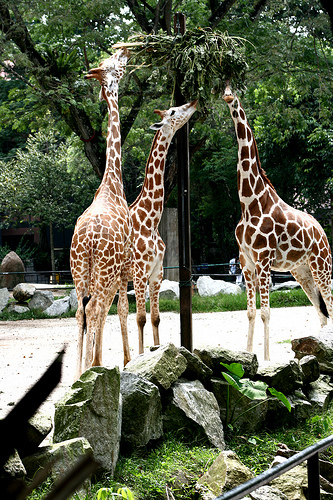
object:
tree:
[0, 127, 101, 288]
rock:
[195, 273, 239, 296]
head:
[147, 101, 198, 139]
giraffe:
[90, 100, 198, 369]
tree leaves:
[288, 110, 296, 122]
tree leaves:
[198, 159, 209, 173]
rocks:
[12, 283, 36, 302]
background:
[0, 0, 332, 499]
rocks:
[52, 366, 120, 474]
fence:
[1, 263, 244, 287]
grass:
[110, 293, 245, 310]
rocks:
[0, 251, 25, 289]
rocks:
[0, 286, 15, 315]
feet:
[262, 356, 271, 367]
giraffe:
[222, 79, 333, 359]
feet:
[244, 343, 254, 351]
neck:
[225, 97, 269, 217]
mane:
[250, 128, 276, 191]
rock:
[160, 375, 225, 453]